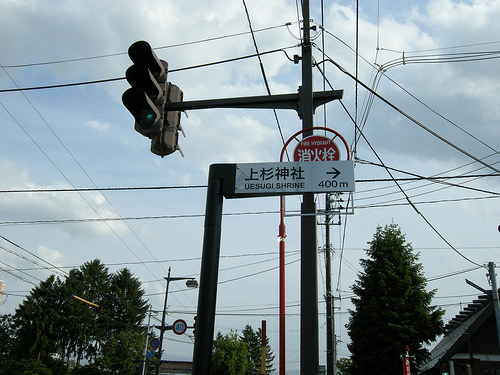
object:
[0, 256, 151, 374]
trees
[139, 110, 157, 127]
green light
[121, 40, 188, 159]
traffic light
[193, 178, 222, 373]
pole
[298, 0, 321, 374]
pole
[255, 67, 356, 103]
wall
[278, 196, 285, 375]
pole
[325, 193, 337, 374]
pole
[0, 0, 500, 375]
sky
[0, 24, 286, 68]
line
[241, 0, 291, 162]
line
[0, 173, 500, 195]
line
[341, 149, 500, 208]
line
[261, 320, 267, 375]
pole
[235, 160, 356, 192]
sign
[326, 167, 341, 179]
arrow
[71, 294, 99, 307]
guard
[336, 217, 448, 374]
tree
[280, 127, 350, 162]
circle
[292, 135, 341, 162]
sign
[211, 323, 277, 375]
tree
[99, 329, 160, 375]
tree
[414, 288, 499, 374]
building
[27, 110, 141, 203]
clouds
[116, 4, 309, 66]
clouds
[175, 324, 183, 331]
number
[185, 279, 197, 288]
street light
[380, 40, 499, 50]
cable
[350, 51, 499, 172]
cable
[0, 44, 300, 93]
cable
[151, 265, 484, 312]
cable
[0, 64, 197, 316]
cable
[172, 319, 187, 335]
sign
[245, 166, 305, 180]
text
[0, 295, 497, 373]
street